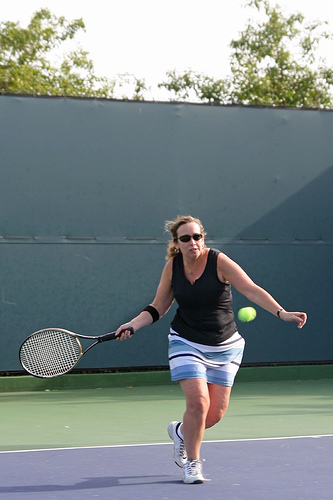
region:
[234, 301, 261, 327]
blurry green tennis ball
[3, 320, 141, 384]
tennis racket in tennis player's hand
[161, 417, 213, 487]
pair of sneakers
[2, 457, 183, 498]
shadow on tennis court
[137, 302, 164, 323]
black arm band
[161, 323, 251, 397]
pair of striped shorts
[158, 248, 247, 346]
black tank top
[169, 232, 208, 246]
pair of black sun glasses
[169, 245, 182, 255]
one hoop earring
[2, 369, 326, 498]
green and grey tennis court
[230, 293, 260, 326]
tennis ball in the air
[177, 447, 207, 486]
woman wearing tennis shoes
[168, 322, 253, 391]
woman wearing stripped shorts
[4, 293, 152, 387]
woman holding a tennis racket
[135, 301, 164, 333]
woman wearing a wristband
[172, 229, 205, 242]
woman wearing black sunglasses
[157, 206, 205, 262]
woman with blonde hair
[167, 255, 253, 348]
woman wearing a black shirt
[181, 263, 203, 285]
woman wearing a necklace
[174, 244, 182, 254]
woman with earring in her ear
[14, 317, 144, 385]
black and white racket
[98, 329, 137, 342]
black handle of racket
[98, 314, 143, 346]
hand holding racket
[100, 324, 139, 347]
hand holding black handles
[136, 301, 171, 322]
black elbow band on arm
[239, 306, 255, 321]
yellow tennis ball in air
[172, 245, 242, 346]
black tank top on woman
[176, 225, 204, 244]
black sunglasses on woman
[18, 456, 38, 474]
purple paint on court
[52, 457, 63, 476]
purple paint on court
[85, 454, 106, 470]
purple paint on court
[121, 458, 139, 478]
purple paint on court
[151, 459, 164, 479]
purple paint on court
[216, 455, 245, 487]
purple paint on court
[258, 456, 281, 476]
purple paint on court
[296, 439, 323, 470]
purple paint on court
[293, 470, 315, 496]
purple paint on court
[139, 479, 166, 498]
purple paint on court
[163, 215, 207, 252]
woman has brown hair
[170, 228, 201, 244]
woman has dark glasses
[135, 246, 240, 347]
woman has black shirt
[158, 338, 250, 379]
blue and white pants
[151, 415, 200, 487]
woman has grey shoes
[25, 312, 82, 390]
black and brown racket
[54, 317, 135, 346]
black grip on racket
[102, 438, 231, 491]
court is dark grey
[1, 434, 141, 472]
white base line behind woman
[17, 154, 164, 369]
green wall behind woman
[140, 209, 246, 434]
woman standing in the field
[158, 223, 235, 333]
woman wearing a back shirt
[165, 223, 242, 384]
woman wearing a blue and white skirt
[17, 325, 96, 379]
silver and black racket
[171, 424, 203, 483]
woman wearing a white shoes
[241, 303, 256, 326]
small green tennis ball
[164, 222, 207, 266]
woman using black sun glasses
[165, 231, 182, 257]
rigth ear woman